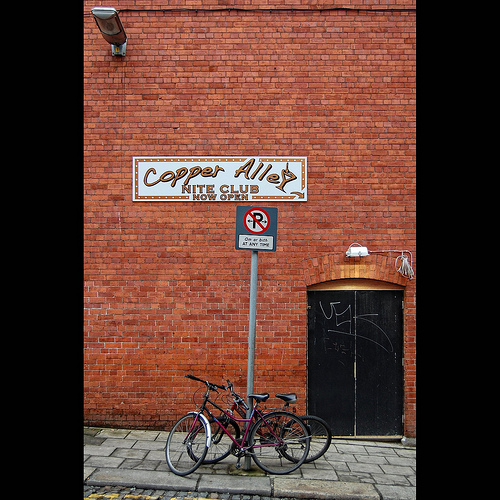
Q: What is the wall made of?
A: Bricks.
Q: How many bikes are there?
A: Two.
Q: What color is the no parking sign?
A: Blue.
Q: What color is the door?
A: Black.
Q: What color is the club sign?
A: White.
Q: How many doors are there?
A: One.